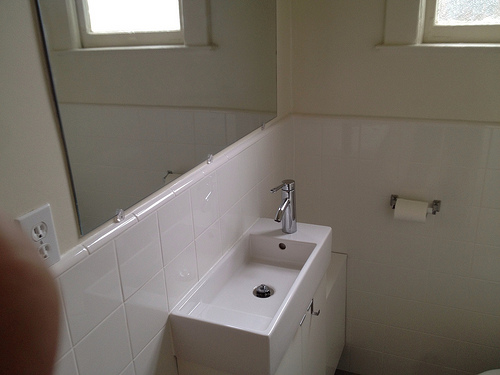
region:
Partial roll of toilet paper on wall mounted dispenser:
[381, 181, 451, 231]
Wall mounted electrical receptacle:
[14, 201, 72, 267]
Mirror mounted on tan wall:
[20, 7, 312, 172]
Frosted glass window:
[416, 4, 498, 59]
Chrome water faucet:
[263, 174, 303, 243]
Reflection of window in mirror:
[54, 2, 245, 63]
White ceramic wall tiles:
[316, 122, 456, 177]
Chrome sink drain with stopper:
[251, 281, 276, 297]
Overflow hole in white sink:
[270, 235, 294, 251]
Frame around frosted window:
[374, 2, 429, 67]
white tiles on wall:
[68, 258, 163, 356]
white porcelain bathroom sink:
[165, 215, 338, 366]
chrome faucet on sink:
[265, 168, 300, 236]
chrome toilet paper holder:
[385, 192, 445, 224]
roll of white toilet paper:
[393, 197, 431, 224]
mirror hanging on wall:
[55, 22, 213, 189]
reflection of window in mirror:
[63, 10, 213, 61]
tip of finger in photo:
[2, 214, 64, 369]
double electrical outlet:
[13, 198, 71, 275]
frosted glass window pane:
[440, 6, 495, 26]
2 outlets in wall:
[15, 206, 63, 267]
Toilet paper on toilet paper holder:
[389, 190, 443, 224]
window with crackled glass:
[428, 3, 495, 31]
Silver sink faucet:
[267, 178, 306, 237]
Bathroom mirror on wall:
[29, 0, 280, 227]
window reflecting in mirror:
[39, 5, 239, 61]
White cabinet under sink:
[266, 277, 339, 372]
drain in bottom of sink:
[247, 278, 279, 300]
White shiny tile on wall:
[321, 116, 359, 157]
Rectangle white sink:
[170, 215, 334, 371]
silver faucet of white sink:
[272, 174, 307, 236]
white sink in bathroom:
[223, 213, 324, 354]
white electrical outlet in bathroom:
[18, 203, 70, 269]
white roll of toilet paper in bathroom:
[379, 184, 446, 237]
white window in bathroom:
[421, 1, 498, 44]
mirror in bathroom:
[43, 3, 269, 130]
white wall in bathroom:
[301, 12, 365, 109]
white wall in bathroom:
[361, 240, 478, 362]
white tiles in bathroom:
[311, 127, 490, 194]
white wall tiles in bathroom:
[71, 262, 152, 354]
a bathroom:
[38, 20, 498, 367]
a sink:
[222, 167, 342, 364]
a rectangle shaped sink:
[175, 176, 349, 341]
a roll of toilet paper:
[381, 177, 468, 232]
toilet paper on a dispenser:
[381, 189, 439, 222]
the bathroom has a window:
[389, 4, 498, 79]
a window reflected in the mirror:
[65, 2, 231, 59]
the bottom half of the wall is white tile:
[51, 135, 498, 362]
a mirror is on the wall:
[23, 4, 321, 212]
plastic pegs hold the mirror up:
[88, 112, 318, 231]